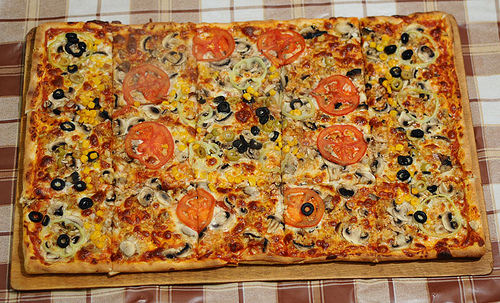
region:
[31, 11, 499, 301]
square pizza on table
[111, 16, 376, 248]
tomato slices on pizza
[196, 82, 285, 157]
black olives on pizza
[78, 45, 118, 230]
corn on pizza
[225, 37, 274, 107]
onion ring on pizza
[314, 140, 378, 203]
pizza pieces on pizza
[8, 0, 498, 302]
wooden coaster under pizza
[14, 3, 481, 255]
rectangular pizza on table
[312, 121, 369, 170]
tomato on the pizza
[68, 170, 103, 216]
olives on the pizza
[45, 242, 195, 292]
crust of the pizza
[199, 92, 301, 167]
middle of the pizza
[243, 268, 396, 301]
tablecloth under the pizza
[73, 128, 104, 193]
yellow topping on the pizza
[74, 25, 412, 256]
many tomatoes on the pizza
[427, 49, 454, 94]
red sauce on the pizza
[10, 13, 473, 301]
pizza with many toppings on it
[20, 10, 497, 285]
This is pizza in a plate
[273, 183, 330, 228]
this is a slice of tomato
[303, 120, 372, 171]
this is a slice of tomato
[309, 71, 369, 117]
this is a slice of tomato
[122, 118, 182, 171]
this is a slice of tomato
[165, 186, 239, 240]
this is a slice of tomato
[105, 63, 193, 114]
this is a slice of tomato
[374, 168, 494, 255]
this is a slice of pizza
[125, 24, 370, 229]
The tomatoes on the pizza.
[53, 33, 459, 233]
The black olives on the pizza.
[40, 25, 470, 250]
The melted cheese on the pizza.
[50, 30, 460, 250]
The pieces of corn on the pizza.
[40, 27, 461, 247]
The circle pieces of onions on the pizza.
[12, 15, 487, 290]
The wooden cutting board.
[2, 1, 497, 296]
The plaid table cloth.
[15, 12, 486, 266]
The crust of the pizza.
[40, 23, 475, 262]
The slices cut into the pizza.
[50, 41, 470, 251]
The green olives on the pizza.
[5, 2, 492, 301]
The tablecloth is plaid.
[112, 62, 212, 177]
There are tomatoes on the pizza.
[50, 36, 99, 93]
There are olives on the pizza.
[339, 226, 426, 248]
There are mushrooms on the pizza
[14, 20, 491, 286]
The pizza is on a brown tray.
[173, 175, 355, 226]
The tomatoes are red.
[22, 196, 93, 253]
The olives are black.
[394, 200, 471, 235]
The mushrooms are light brown.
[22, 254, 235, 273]
The pizza crust is light brown.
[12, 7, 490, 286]
Tomato, mushroom and black olive pizza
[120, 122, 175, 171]
Thinnly sliced ripe tomato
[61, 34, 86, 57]
Slice of black olive